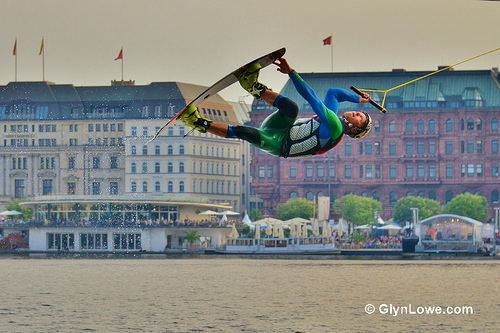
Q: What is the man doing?
A: Skiing in the air.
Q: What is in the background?
A: Two large buildings.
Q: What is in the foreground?
A: Sand.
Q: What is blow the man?
A: Water.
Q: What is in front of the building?
A: A line of trees.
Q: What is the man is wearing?
A: Wetsuit.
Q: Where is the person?
A: In the air.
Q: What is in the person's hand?
A: A handle.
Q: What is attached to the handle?
A: A rope.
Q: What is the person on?
A: A ski board.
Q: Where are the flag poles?
A: On the buildings.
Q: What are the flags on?
A: The flagpoles.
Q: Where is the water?
A: Under the person.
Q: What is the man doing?
A: Kite surfing.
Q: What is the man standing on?
A: Kiteboard.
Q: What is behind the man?
A: Buildings.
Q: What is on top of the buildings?
A: Flags.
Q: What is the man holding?
A: A Handle.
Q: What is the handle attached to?
A: A Rope.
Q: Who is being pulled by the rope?
A: The Man.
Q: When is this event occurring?
A: Daytime.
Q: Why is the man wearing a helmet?
A: To Prevent Head Injury.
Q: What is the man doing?
A: Wakeboarding.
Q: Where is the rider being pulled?
A: On the Water.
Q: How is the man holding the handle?
A: With one hand.